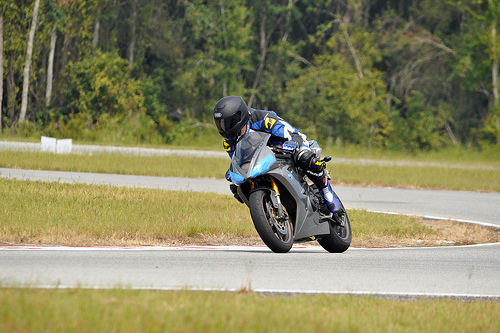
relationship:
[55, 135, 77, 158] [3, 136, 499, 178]
sign near road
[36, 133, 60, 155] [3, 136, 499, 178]
sign near road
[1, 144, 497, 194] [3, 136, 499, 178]
grass by road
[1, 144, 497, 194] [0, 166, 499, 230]
grass by road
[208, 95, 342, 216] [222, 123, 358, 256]
person riding motorcycle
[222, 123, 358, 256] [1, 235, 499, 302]
motorcycle on road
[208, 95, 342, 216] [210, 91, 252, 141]
person wearing helmet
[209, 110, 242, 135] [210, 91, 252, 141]
visor on helmet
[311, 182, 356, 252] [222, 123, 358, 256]
tires on motorcycle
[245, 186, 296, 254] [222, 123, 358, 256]
tires on motorcycle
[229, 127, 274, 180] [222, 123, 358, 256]
windshield on motorcycle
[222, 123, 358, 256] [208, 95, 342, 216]
motorcycle under person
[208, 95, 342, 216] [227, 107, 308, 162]
person wearing jacket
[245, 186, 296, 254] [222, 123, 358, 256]
tires of motorcycle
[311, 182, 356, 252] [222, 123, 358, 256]
tires of motorcycle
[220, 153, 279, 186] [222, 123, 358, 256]
stripe on motorcycle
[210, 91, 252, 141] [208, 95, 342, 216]
helmet on person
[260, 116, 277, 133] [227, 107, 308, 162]
patch on jacket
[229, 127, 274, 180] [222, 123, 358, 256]
windshield of motorcycle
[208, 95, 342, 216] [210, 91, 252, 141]
person with helmet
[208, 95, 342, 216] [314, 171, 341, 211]
person wearing boot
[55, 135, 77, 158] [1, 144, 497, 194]
sign on grass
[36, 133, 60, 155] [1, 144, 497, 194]
sign on grass